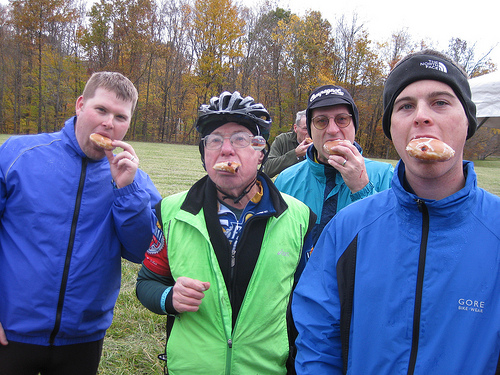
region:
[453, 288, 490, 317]
white on blue text reading 'GORE'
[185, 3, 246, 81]
deciduous tree showing fall leaves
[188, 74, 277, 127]
black and gray bicycle helmet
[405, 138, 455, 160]
berry danish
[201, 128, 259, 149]
worn clear glasses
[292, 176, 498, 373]
blue and black colored windbreaker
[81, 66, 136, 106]
high and tight style haircut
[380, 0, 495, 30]
cold white Autumn sky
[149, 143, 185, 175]
harvested field of alfalfa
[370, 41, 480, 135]
man's head with a black beanie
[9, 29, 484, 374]
men eating doughnuts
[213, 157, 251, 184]
a doughnut with a dollp of jelly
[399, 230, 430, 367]
a black zipper on a blue jacket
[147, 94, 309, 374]
a man wearing eye glasses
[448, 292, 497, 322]
a logo on the jacket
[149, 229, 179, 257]
a colorful patch on a red sleeve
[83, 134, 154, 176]
a hand grasping a doughnut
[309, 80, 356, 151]
a man wearing a black hat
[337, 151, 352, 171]
a silver ring on a finger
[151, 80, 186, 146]
trees with yellow leaves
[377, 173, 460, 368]
a man in blue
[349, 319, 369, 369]
a man in blue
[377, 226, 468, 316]
a man in blue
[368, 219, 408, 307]
a man in blue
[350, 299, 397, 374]
a man in blue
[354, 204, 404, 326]
a man in blue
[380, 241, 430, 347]
a man in blue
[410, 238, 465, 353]
a man in blue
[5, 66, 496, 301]
five men eating doughnuts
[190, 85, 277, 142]
a man wearing a black and silver helmet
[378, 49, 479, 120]
man wearing a black wool hat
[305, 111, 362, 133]
man wearing glasses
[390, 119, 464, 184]
man with a doughnut in his mouth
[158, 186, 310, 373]
man wearing a green windbreaker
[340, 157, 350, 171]
man wearing a wedding ring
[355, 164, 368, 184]
man with a red scratch on his hand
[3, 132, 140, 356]
man wearing a blue windbreaker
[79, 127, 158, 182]
man holding a doughnut in his hand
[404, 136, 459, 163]
Fruit filled breakfast pastery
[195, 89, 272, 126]
Black safety bicycle helmet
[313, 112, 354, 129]
Pair of eyewear glasses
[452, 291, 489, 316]
GORE logo on jacket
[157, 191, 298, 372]
Green and black jacket vest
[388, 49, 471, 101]
Back toboggan with logo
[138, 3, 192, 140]
Group of large fall trees in background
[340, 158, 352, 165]
Silver tone wedding band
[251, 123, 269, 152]
Refective helmet mirror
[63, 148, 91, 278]
Long black zipper on jacket